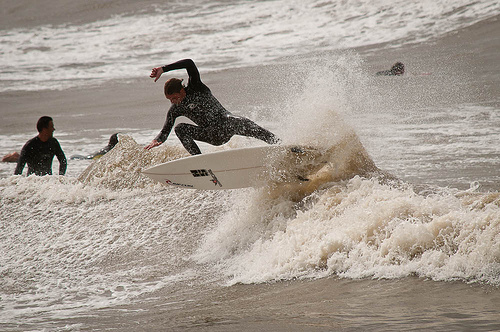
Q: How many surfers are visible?
A: Two.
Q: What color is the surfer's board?
A: White.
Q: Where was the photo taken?
A: In the ocean.